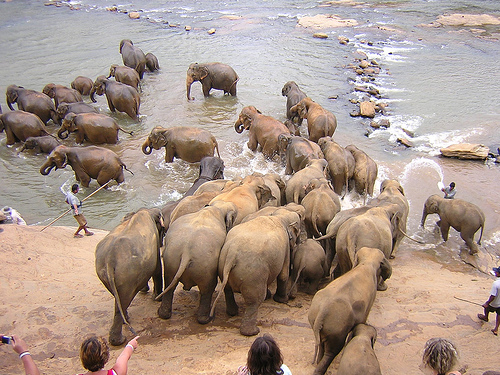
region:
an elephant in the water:
[182, 61, 241, 101]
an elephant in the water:
[141, 124, 220, 165]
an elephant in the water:
[233, 104, 288, 160]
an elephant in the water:
[289, 96, 335, 140]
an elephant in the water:
[55, 110, 122, 144]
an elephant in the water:
[89, 74, 138, 119]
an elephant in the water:
[6, 83, 53, 119]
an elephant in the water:
[418, 188, 488, 253]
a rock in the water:
[438, 135, 493, 165]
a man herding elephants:
[62, 175, 119, 240]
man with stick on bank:
[49, 181, 113, 241]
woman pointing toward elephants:
[77, 329, 144, 373]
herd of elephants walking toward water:
[207, 161, 369, 266]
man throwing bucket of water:
[427, 153, 461, 200]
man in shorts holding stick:
[447, 266, 498, 332]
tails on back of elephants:
[97, 249, 243, 321]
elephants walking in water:
[232, 111, 291, 178]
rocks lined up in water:
[373, 116, 475, 162]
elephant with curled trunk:
[135, 121, 181, 164]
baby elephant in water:
[137, 46, 168, 78]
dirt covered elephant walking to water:
[97, 200, 172, 342]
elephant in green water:
[174, 55, 248, 100]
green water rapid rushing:
[350, 50, 408, 107]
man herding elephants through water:
[52, 178, 109, 242]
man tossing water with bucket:
[391, 153, 466, 196]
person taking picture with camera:
[0, 325, 59, 373]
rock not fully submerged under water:
[436, 132, 491, 167]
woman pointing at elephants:
[65, 325, 148, 374]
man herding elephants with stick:
[444, 259, 498, 346]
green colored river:
[249, 21, 455, 80]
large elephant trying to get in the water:
[148, 200, 254, 332]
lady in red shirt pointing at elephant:
[71, 333, 164, 374]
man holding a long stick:
[40, 178, 119, 240]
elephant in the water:
[141, 127, 236, 162]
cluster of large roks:
[329, 36, 420, 152]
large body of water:
[16, 17, 111, 64]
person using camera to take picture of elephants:
[0, 323, 42, 371]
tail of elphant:
[153, 251, 198, 311]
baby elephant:
[18, 136, 62, 158]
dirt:
[13, 227, 93, 318]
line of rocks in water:
[350, 54, 397, 121]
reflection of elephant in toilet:
[189, 100, 248, 126]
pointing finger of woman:
[85, 330, 142, 370]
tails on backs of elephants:
[101, 248, 241, 330]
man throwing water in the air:
[429, 164, 461, 204]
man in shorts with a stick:
[457, 265, 499, 332]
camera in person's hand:
[1, 325, 31, 371]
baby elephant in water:
[15, 133, 68, 157]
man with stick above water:
[37, 175, 116, 242]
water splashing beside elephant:
[236, 145, 283, 177]